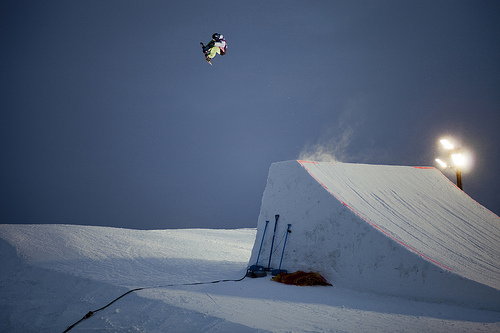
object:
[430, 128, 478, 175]
lights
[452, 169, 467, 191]
pole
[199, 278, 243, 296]
wire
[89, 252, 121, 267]
ground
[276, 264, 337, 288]
cloth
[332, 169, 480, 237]
snow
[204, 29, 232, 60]
man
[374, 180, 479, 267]
ramp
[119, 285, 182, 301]
cord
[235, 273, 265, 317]
ramp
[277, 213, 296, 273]
poles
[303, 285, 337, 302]
ramp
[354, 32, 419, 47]
sky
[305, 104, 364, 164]
dust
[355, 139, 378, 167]
ramp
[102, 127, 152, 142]
air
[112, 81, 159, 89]
air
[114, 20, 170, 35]
air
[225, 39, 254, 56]
skies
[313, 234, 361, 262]
ramp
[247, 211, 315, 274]
equipment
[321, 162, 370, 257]
ramp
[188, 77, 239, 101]
midair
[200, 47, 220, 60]
leg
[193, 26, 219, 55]
snowboarding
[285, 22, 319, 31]
air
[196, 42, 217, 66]
skis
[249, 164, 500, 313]
hill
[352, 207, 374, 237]
ramp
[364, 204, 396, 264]
snow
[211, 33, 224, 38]
helmet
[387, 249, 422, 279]
snow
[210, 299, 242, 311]
ground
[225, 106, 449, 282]
picture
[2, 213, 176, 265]
mountain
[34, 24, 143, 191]
picture